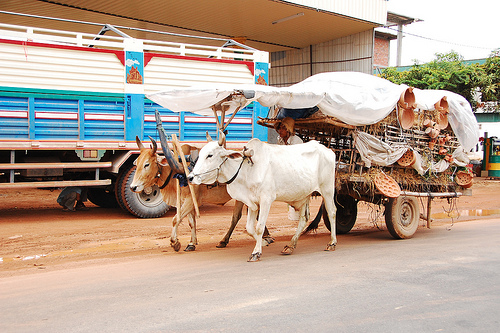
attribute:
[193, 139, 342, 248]
cow — white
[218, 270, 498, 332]
road — dirty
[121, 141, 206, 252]
cow — brown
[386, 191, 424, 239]
wheel — brown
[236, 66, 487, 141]
cloth — white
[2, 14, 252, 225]
cart — parked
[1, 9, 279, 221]
cart — white, blue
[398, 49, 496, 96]
trees — green